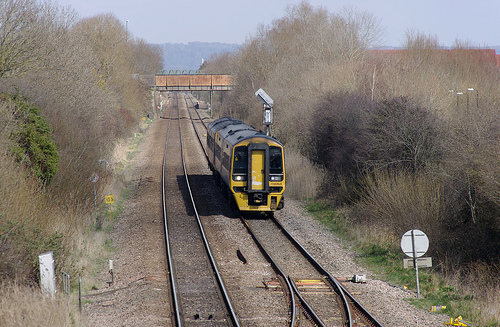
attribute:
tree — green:
[0, 83, 62, 198]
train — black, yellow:
[192, 81, 307, 224]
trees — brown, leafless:
[312, 53, 459, 187]